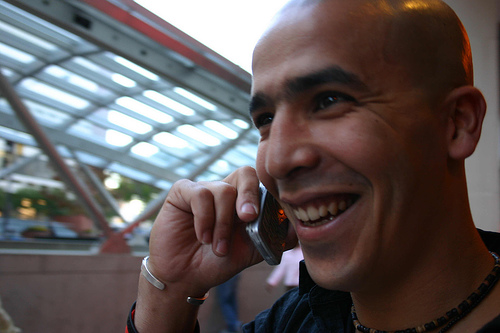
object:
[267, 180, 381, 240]
smile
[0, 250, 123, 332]
wall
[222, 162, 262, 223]
fingers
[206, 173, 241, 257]
fingers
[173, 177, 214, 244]
fingers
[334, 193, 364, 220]
ground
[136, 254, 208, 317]
wrist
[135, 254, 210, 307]
silver bracelet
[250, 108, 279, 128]
eye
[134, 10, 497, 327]
man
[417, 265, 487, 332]
necklace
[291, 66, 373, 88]
eyebrows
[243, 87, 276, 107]
eyebrows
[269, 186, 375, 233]
big smile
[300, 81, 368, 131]
eye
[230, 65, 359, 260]
man's face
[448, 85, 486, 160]
ear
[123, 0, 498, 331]
bald man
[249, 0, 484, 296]
head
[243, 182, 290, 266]
cellphone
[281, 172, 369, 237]
mouth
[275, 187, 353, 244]
teeth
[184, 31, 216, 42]
nothing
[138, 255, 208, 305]
watch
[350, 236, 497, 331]
neck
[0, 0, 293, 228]
sky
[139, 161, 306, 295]
hand